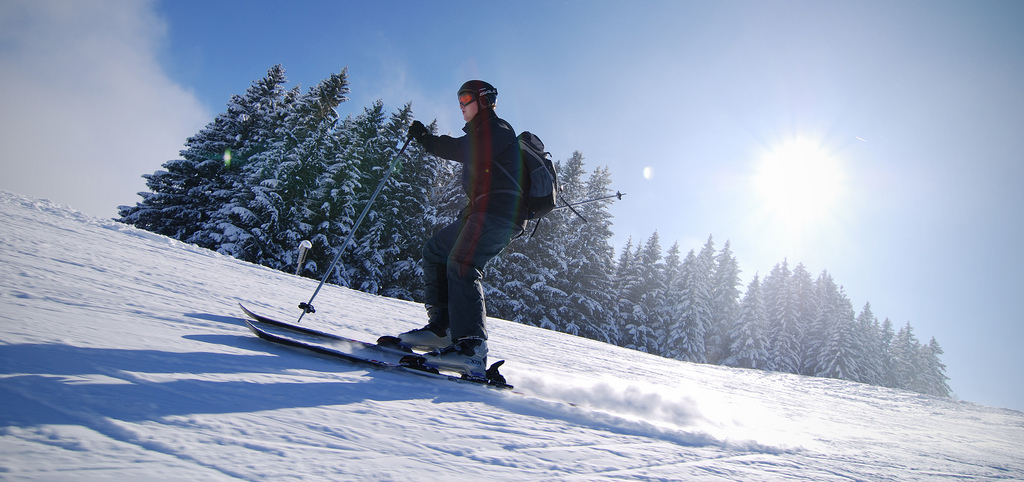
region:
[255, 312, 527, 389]
man is wearing skiing shoes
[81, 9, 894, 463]
the man is wearing snow ski gear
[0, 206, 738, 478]
white snow is on the ground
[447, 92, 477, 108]
man has red goggles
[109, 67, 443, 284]
snow covered trees in the back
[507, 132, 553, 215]
gray and black backpack is on his back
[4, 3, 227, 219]
clouds are in the cky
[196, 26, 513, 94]
the sky is light blue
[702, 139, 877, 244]
the sun is shining brightly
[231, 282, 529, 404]
the skies are blak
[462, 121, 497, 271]
the arm of the jacket is red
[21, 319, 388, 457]
the shadow is dark on the dnow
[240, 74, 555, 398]
man with backpack and poles skiing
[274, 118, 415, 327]
ski pole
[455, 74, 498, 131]
head of man skiing with orange goggles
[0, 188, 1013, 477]
snow covered ski slope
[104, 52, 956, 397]
snow covered pine trees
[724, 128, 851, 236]
halo of the sun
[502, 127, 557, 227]
dark colored backpack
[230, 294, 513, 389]
pair of skis and boots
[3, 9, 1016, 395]
blue sky with a cloud and sun halo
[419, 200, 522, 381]
dark colored snow pants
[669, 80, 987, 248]
Glare from the sun shining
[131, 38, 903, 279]
Snow covered evergreens in the distance.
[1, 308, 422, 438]
Shadow of a skier on the snow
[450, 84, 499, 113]
Ski goggles on a person's head.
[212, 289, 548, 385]
Pair of skis resting on the snow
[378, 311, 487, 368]
Pair of ski boots on a man's feet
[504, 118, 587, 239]
Dark colored back pack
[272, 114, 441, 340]
Ski pole in man's gloved hand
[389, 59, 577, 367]
Skier wearing ski bibs and jacket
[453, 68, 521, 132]
Black helmet on skier's head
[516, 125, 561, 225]
backpack on skier's back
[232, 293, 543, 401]
skies on man's feet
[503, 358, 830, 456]
snow being kicked up by skies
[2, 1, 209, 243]
a cloud in the distance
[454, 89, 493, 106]
goggles on a man's face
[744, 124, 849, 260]
the sun over a clump of trees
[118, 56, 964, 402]
a clump of trees behind the skier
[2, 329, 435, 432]
shadows on the snow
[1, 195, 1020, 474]
ground is sloping upwards towards the left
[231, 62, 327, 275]
snow on pine trees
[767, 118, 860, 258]
a bright glaring sun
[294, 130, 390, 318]
a ski pole held in the right hand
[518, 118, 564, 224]
a dark back-pack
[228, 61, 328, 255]
evergreens with fresh snow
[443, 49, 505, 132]
a skiers head wearing goggles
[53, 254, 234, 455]
a long shadow cast in the snow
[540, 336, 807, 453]
powdery snow kicked up by the ski's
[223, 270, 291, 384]
tips of ski's carving on the slope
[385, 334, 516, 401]
a ski boot with bindings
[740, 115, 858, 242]
a bright white sun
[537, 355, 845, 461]
a trail of disturbed snow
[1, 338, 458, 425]
a shadow on the snow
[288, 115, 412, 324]
a ski pole held at an angle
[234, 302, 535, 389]
a pair of skies gliding over the snow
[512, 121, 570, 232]
a backpack being worn by a skier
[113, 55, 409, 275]
tall pine trees covered in snow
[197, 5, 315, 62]
a patch of pristine blue sky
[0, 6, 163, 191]
white hazy clouds in the sky